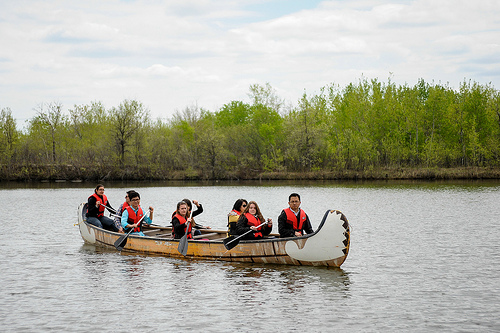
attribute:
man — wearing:
[276, 192, 315, 237]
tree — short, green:
[242, 91, 304, 173]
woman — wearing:
[86, 180, 116, 234]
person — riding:
[171, 200, 192, 235]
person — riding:
[272, 190, 313, 237]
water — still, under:
[7, 183, 494, 331]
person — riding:
[277, 192, 309, 237]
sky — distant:
[28, 28, 487, 90]